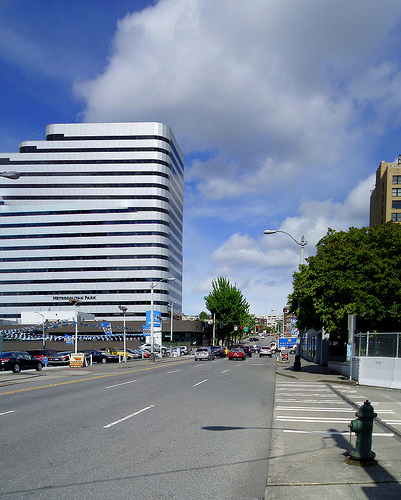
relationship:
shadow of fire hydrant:
[368, 466, 401, 498] [349, 396, 381, 458]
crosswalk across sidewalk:
[278, 373, 365, 434] [262, 353, 401, 500]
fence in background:
[337, 331, 400, 374] [1, 69, 401, 383]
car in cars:
[227, 344, 243, 366] [193, 347, 216, 361]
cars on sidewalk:
[193, 347, 216, 361] [262, 353, 401, 500]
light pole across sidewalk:
[263, 207, 310, 338] [262, 353, 401, 500]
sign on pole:
[73, 351, 87, 370] [68, 302, 78, 357]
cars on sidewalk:
[196, 348, 271, 372] [262, 353, 401, 500]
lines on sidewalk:
[55, 366, 157, 434] [262, 353, 401, 500]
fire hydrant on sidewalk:
[349, 396, 381, 458] [266, 353, 399, 498]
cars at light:
[196, 348, 271, 372] [238, 320, 263, 335]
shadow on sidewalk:
[368, 466, 401, 498] [266, 353, 399, 498]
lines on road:
[102, 403, 156, 428] [72, 331, 286, 454]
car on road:
[1, 348, 44, 380] [72, 331, 286, 454]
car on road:
[227, 344, 243, 366] [72, 331, 286, 454]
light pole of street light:
[300, 234, 306, 265] [260, 216, 316, 254]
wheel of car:
[32, 364, 44, 372] [1, 348, 44, 380]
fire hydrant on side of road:
[349, 396, 381, 458] [72, 331, 286, 454]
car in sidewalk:
[227, 344, 243, 366] [262, 353, 401, 500]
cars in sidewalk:
[193, 347, 216, 361] [262, 353, 401, 500]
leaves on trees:
[353, 253, 367, 273] [215, 221, 397, 332]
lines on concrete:
[55, 366, 157, 434] [70, 368, 318, 490]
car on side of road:
[1, 348, 44, 380] [72, 331, 286, 454]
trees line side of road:
[215, 221, 397, 332] [72, 331, 286, 454]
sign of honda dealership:
[73, 351, 87, 370] [4, 117, 190, 372]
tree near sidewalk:
[285, 247, 401, 324] [262, 353, 401, 500]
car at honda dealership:
[1, 348, 44, 380] [4, 117, 190, 372]